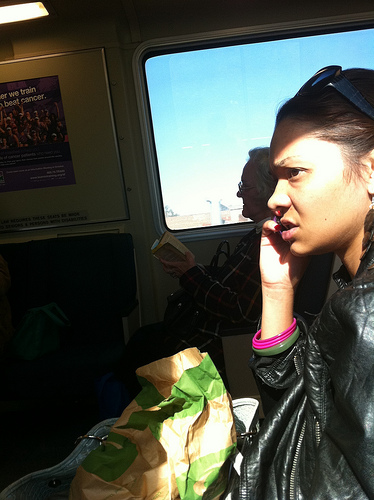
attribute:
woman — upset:
[237, 61, 373, 291]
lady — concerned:
[271, 90, 369, 499]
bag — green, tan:
[105, 356, 236, 496]